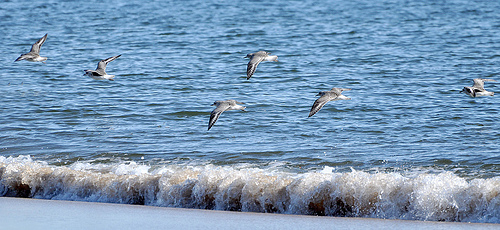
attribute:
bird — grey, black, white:
[13, 29, 51, 69]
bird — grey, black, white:
[82, 52, 127, 91]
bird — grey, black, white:
[241, 46, 277, 82]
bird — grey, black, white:
[203, 95, 248, 136]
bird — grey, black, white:
[303, 81, 351, 118]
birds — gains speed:
[32, 22, 497, 153]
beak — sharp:
[458, 89, 463, 94]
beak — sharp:
[311, 92, 319, 97]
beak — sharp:
[241, 55, 248, 60]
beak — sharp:
[209, 102, 214, 108]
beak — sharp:
[81, 68, 88, 73]